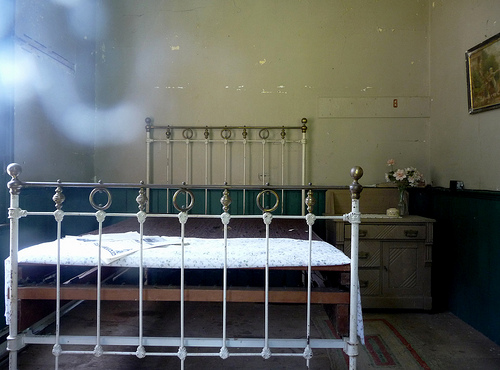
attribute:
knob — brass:
[350, 165, 362, 179]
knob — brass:
[7, 162, 20, 176]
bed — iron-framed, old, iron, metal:
[6, 119, 361, 369]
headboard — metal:
[142, 116, 309, 184]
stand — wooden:
[16, 282, 349, 335]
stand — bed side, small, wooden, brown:
[326, 184, 437, 311]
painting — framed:
[465, 31, 499, 114]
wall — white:
[426, 3, 498, 344]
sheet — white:
[0, 229, 365, 348]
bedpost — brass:
[344, 165, 365, 367]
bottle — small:
[399, 182, 411, 215]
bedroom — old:
[0, 1, 498, 369]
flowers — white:
[382, 166, 425, 187]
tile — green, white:
[403, 95, 432, 119]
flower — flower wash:
[369, 159, 429, 218]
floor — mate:
[1, 288, 494, 370]